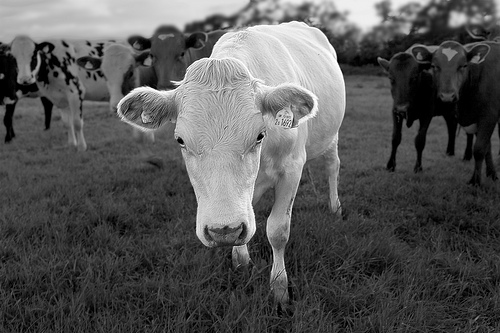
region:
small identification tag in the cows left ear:
[270, 101, 291, 129]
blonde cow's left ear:
[112, 82, 172, 132]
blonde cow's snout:
[190, 212, 255, 247]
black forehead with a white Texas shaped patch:
[430, 38, 470, 68]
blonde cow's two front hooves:
[229, 249, 293, 306]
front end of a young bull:
[377, 49, 431, 173]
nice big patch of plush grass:
[0, 170, 185, 331]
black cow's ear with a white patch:
[74, 56, 100, 73]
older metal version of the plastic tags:
[195, 37, 210, 52]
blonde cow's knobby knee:
[264, 221, 291, 251]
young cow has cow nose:
[200, 218, 252, 248]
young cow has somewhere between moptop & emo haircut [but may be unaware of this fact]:
[160, 55, 265, 97]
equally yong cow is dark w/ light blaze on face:
[436, 40, 463, 63]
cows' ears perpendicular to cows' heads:
[0, 20, 490, 305]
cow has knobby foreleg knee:
[260, 178, 307, 254]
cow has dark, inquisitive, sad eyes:
[164, 126, 273, 158]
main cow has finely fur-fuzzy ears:
[109, 77, 319, 143]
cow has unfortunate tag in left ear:
[268, 101, 296, 134]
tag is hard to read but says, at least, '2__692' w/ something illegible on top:
[267, 105, 302, 131]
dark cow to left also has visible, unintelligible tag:
[465, 50, 487, 67]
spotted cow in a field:
[3, 30, 146, 138]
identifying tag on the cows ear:
[262, 102, 304, 134]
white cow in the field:
[115, 12, 357, 322]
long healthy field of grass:
[12, 229, 172, 315]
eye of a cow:
[242, 125, 269, 149]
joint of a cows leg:
[259, 202, 301, 255]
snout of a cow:
[184, 198, 266, 252]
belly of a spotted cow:
[67, 78, 124, 110]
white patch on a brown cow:
[413, 37, 498, 115]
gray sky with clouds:
[7, 7, 156, 31]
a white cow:
[111, 9, 362, 325]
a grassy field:
[1, 66, 498, 329]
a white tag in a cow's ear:
[268, 102, 301, 133]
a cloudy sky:
[1, 3, 241, 40]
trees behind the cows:
[349, 3, 497, 53]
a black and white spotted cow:
[8, 30, 138, 150]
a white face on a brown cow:
[73, 45, 163, 105]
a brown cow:
[374, 37, 449, 172]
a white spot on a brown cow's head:
[438, 44, 463, 66]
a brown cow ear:
[186, 28, 210, 53]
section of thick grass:
[7, 217, 187, 317]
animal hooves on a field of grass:
[375, 140, 495, 185]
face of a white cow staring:
[105, 50, 320, 250]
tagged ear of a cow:
[260, 75, 320, 135]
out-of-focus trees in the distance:
[320, 0, 495, 35]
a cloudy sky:
[0, 0, 145, 30]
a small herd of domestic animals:
[5, 20, 470, 270]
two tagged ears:
[100, 60, 315, 130]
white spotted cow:
[5, 25, 110, 90]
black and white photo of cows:
[5, 10, 420, 305]